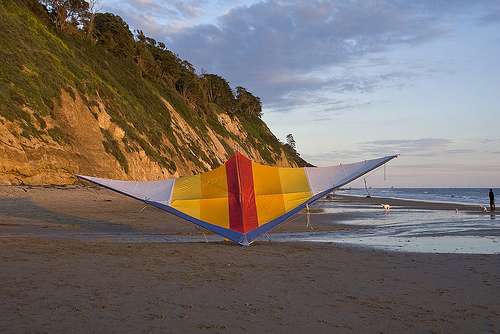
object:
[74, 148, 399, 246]
kite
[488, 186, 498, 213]
person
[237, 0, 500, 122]
sky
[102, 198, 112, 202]
rock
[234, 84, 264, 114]
trees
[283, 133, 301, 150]
trees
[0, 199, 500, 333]
beach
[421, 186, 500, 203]
water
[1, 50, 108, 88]
grass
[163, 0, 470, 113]
cloud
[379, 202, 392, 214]
dog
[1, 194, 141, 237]
shadow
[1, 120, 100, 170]
dirt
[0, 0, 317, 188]
hill